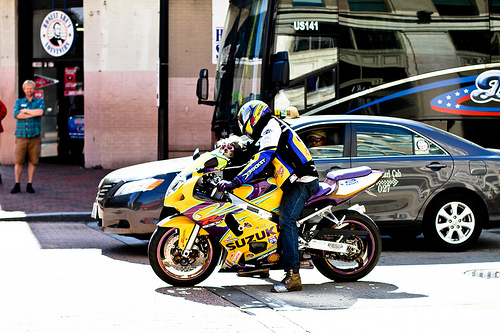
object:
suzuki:
[206, 212, 296, 262]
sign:
[37, 10, 75, 57]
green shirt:
[13, 95, 46, 137]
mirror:
[196, 68, 208, 104]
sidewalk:
[2, 169, 109, 230]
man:
[7, 80, 46, 194]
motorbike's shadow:
[157, 280, 428, 310]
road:
[0, 220, 500, 333]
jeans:
[279, 171, 319, 272]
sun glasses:
[308, 138, 323, 143]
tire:
[422, 188, 486, 252]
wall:
[122, 67, 194, 139]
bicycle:
[148, 99, 385, 293]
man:
[216, 99, 320, 294]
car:
[90, 115, 500, 252]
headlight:
[112, 178, 165, 197]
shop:
[14, 12, 168, 174]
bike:
[147, 135, 385, 287]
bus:
[192, 0, 500, 232]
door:
[14, 0, 85, 171]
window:
[356, 127, 446, 157]